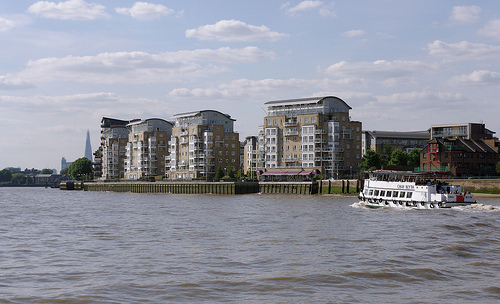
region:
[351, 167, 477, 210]
white tour boat on river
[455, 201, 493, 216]
waves on river from white boat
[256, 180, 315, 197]
green boat dock on rivers edge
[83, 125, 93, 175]
sky scrapper in background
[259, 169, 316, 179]
red awning on tan building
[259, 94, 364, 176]
tan apartment building by river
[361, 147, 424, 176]
green trees in the middle of buildings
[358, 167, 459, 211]
white boat ont he water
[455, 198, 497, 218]
wake from the boat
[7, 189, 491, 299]
ripples on the water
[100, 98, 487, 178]
buildings along the waterway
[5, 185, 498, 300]
waterway the boat is on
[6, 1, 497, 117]
clouds in the sky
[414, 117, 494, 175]
brick building on the right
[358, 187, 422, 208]
windows on the boat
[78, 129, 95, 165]
steeple of building in the distance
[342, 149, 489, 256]
this is a boat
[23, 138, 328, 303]
the water is brown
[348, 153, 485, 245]
the boat is white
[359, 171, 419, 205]
row of boat windows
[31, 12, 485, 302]
a bright and sunny day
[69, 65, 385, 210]
buildings next to water way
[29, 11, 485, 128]
multiple fluffy clouds in sky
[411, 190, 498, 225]
white break of wave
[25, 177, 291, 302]
the water is calm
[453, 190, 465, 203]
red color on back of boat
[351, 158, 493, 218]
white passenger boat travelling on the water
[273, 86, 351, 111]
curved roof on tall building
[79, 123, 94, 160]
tall triangle building in the distance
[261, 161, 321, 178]
purple roof on building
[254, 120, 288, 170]
white windows in building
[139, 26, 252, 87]
white clouds in the sky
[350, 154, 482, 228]
White boat in the water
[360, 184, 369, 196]
Small window on a boat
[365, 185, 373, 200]
Small window on a boat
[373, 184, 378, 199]
Small window on a boat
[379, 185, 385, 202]
Small window on a boat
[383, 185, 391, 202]
Small window on a boat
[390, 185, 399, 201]
Small window on a boat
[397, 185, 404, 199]
Small window on a boat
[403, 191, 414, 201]
Small window on a boat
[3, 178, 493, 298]
Ripples in the water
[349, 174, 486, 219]
a white boat in the water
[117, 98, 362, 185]
three similar buildings in a row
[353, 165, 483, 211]
a ferry in the water